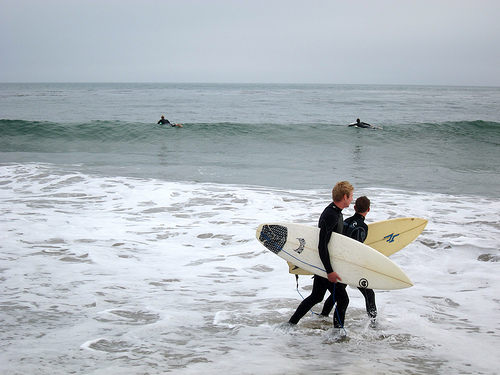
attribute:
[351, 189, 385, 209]
hair — short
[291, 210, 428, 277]
surfboard — beige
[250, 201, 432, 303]
surfboard — white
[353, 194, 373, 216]
hair — brown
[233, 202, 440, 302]
board — surf, design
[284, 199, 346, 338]
wet suit — black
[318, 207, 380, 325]
wet suit — black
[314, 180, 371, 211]
hair — blonde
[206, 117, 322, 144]
wave — small, rolling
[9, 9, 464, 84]
cloudy sky — gray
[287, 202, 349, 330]
man — black wetsuit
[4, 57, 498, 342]
ocean — grey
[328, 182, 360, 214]
hair — dark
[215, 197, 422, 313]
surfboard — Pale yellow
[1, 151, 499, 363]
foam — white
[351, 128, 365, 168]
reflection — surfer